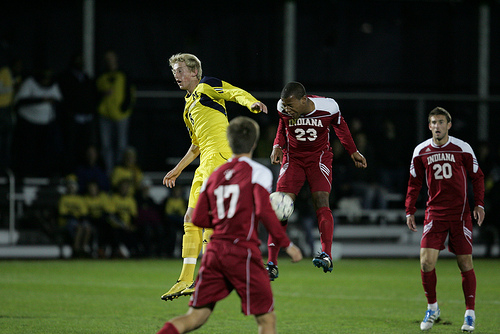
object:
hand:
[161, 167, 183, 189]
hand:
[250, 101, 269, 116]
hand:
[350, 150, 368, 168]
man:
[264, 80, 369, 282]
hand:
[269, 146, 285, 165]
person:
[56, 173, 95, 259]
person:
[82, 179, 120, 260]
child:
[111, 178, 148, 259]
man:
[401, 103, 490, 333]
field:
[0, 241, 500, 333]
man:
[152, 114, 304, 334]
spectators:
[92, 45, 138, 179]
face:
[430, 114, 448, 140]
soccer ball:
[268, 191, 296, 222]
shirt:
[271, 94, 359, 156]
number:
[293, 127, 318, 142]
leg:
[311, 159, 336, 274]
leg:
[263, 160, 304, 282]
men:
[158, 50, 271, 302]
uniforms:
[402, 134, 487, 313]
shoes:
[460, 312, 477, 333]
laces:
[422, 309, 437, 323]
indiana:
[287, 117, 324, 128]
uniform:
[173, 74, 263, 285]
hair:
[427, 106, 452, 124]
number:
[212, 183, 242, 221]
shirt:
[189, 154, 293, 251]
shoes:
[159, 279, 198, 302]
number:
[432, 162, 453, 180]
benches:
[308, 207, 500, 263]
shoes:
[310, 250, 337, 273]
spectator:
[10, 60, 68, 193]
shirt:
[12, 75, 64, 126]